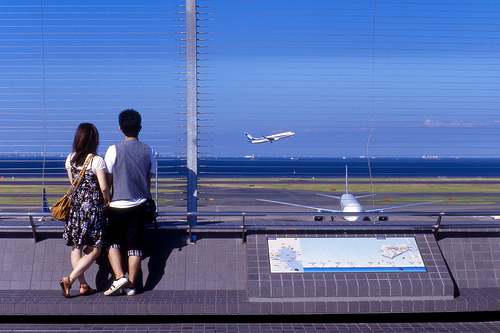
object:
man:
[99, 109, 157, 295]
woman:
[57, 120, 114, 298]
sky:
[0, 0, 499, 157]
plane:
[242, 129, 295, 144]